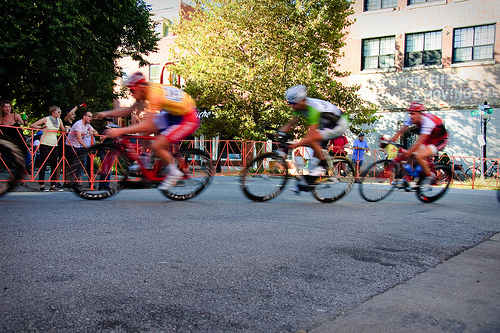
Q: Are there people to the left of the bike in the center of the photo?
A: Yes, there is a person to the left of the bike.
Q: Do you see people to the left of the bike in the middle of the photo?
A: Yes, there is a person to the left of the bike.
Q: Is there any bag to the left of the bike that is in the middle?
A: No, there is a person to the left of the bike.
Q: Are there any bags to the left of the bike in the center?
A: No, there is a person to the left of the bike.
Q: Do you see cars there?
A: No, there are no cars.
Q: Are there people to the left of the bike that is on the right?
A: Yes, there is a person to the left of the bike.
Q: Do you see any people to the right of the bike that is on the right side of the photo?
A: No, the person is to the left of the bike.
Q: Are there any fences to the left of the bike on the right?
A: No, there is a person to the left of the bike.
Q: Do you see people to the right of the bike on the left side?
A: Yes, there is a person to the right of the bike.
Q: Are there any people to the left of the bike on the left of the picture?
A: No, the person is to the right of the bike.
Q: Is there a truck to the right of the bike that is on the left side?
A: No, there is a person to the right of the bike.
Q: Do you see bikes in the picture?
A: Yes, there is a bike.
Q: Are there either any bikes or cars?
A: Yes, there is a bike.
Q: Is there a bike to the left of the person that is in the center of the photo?
A: Yes, there is a bike to the left of the person.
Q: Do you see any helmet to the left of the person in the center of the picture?
A: No, there is a bike to the left of the person.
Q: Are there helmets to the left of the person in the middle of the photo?
A: No, there is a bike to the left of the person.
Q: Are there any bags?
A: No, there are no bags.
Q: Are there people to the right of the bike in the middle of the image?
A: Yes, there is a person to the right of the bike.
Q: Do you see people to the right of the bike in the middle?
A: Yes, there is a person to the right of the bike.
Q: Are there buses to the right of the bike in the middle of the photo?
A: No, there is a person to the right of the bike.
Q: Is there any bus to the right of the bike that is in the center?
A: No, there is a person to the right of the bike.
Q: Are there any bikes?
A: Yes, there is a bike.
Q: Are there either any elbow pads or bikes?
A: Yes, there is a bike.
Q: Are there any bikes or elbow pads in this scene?
A: Yes, there is a bike.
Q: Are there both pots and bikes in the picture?
A: No, there is a bike but no pots.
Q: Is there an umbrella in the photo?
A: No, there are no umbrellas.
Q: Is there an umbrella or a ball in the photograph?
A: No, there are no umbrellas or balls.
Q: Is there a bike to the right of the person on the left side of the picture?
A: Yes, there is a bike to the right of the person.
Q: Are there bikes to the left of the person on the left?
A: No, the bike is to the right of the person.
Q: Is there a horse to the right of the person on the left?
A: No, there is a bike to the right of the person.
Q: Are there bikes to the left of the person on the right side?
A: Yes, there is a bike to the left of the person.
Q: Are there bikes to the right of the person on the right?
A: No, the bike is to the left of the person.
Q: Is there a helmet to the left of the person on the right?
A: No, there is a bike to the left of the person.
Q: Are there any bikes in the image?
A: Yes, there is a bike.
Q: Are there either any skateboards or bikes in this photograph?
A: Yes, there is a bike.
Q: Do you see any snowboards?
A: No, there are no snowboards.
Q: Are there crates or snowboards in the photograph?
A: No, there are no snowboards or crates.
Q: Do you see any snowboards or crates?
A: No, there are no snowboards or crates.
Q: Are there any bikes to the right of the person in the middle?
A: Yes, there is a bike to the right of the person.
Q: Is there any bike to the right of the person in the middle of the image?
A: Yes, there is a bike to the right of the person.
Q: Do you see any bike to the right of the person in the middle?
A: Yes, there is a bike to the right of the person.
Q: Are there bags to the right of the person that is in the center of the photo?
A: No, there is a bike to the right of the person.